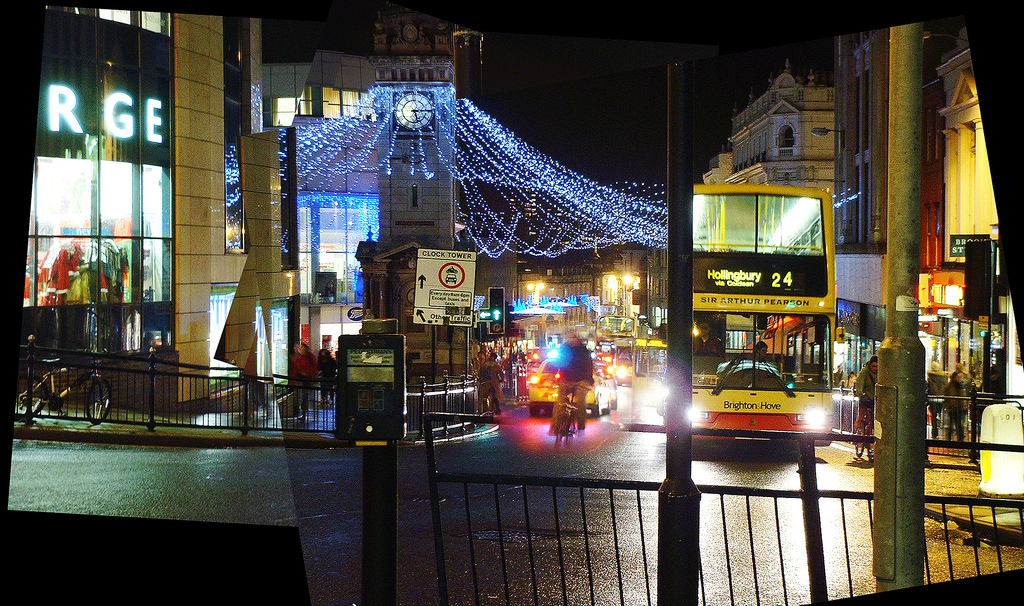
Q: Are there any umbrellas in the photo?
A: No, there are no umbrellas.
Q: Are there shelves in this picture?
A: No, there are no shelves.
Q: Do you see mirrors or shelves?
A: No, there are no shelves or mirrors.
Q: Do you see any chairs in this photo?
A: No, there are no chairs.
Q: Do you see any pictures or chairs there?
A: No, there are no chairs or pictures.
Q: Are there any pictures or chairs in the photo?
A: No, there are no chairs or pictures.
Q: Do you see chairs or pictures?
A: No, there are no chairs or pictures.